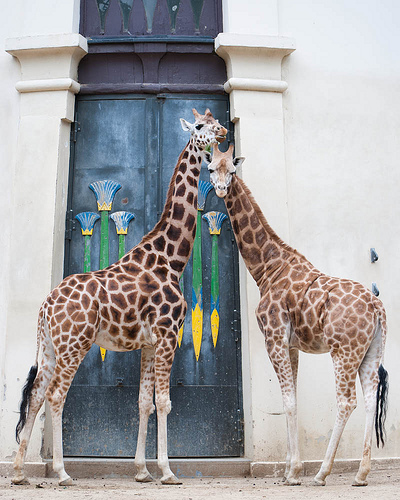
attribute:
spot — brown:
[241, 229, 253, 243]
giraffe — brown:
[8, 117, 213, 446]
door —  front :
[58, 50, 243, 457]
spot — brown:
[167, 225, 182, 240]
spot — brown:
[254, 223, 268, 247]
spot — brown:
[259, 259, 282, 285]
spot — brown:
[176, 241, 193, 255]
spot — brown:
[144, 243, 158, 270]